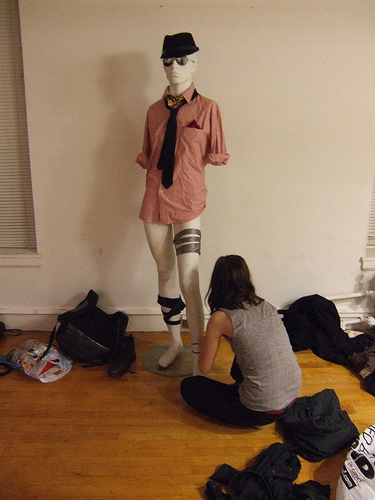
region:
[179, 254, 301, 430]
woman sitting on floor working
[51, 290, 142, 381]
black backpack and boot on floor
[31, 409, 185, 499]
light brown hardwood floor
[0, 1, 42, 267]
window with miniblinds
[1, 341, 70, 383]
plastic shopping bag on floor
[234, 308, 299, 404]
grey sleaveless shirt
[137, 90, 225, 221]
shirt with necktie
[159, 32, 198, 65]
hat and sunglasses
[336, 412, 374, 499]
Bed Bath and Beyond plastic bag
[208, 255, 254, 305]
back of woman's head with brunette hair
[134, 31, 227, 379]
Mannequin wearing black tie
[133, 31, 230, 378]
Mannequin wearing black hat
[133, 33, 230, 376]
Mannequin wearing pink shirt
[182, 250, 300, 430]
Woman sitting on floor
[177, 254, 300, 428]
woman wearing gray shirt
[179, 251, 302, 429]
woman wearing black pants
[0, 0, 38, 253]
window covered with blind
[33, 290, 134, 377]
backpack laying on floor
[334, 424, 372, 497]
plastic bag laying on floor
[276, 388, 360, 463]
pile of fabric behind woman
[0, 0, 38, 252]
part of a window's blinds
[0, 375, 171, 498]
part of a hardwood floor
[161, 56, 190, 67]
black sunglasses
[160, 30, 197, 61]
a small black hat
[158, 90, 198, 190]
a long black tie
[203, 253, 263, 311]
a woman's brown hair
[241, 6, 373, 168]
part of a painted white wall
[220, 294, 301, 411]
a woman's gray tank top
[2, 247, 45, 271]
part of a white window frame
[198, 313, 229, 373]
the arm of a woman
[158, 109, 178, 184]
the tie is black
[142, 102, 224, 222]
the shirt is ornge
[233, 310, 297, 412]
the vest is grey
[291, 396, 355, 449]
the clothes are black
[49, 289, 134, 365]
the bag is on the floor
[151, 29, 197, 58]
the hat is black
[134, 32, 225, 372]
the manequin has glasses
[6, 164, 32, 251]
the blinds are closed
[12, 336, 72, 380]
the paperbag has clothes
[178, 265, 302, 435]
the woman is sitted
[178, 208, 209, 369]
A manquins left leg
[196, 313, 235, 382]
A womans left arm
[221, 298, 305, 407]
A woman in grey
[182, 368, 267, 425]
Black womens long pants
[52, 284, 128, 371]
A bag on floor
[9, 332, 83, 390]
A platic bag on floor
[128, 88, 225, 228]
A mans dress shirt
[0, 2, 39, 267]
A window with shade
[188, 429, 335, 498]
Clothes on the floor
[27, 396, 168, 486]
A yellow hard wood